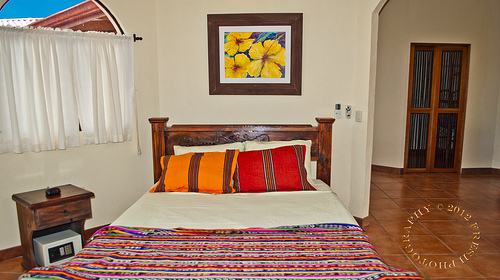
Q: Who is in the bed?
A: No one.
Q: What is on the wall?
A: Picture.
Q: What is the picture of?
A: Flower.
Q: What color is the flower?
A: Yellow.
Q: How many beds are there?
A: One.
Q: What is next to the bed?
A: Nightstand.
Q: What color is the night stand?
A: Brown.